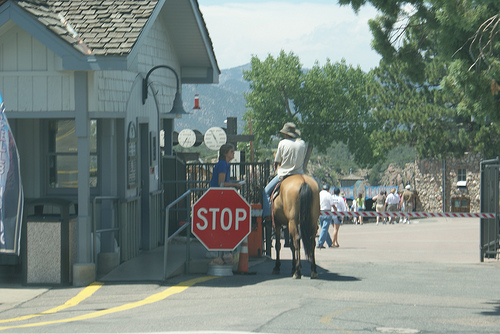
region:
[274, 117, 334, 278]
man riding a horse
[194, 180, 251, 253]
stop sign at the gate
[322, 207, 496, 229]
post is red and white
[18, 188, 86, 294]
trash can next to a building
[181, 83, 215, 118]
bird feeder hanging from roof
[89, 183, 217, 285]
railing to walk up to building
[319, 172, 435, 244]
people walking behind gate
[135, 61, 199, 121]
light hanging from the building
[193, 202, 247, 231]
stop is written in white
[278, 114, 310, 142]
man is wearing a hat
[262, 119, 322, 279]
a person on horseback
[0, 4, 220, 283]
part of a grey structure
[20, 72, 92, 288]
large stationary trash receptacle beside a pillar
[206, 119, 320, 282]
woman looking towards person mounted on horse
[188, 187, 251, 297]
a large stop sign close to the ground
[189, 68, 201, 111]
a hanging bird feeder with red liquid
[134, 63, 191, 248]
light on curved pole above entrance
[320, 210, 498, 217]
red and white striped barrier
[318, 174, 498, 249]
people walking around beyond barrier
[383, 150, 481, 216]
a structure with a stone wall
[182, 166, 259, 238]
red and white sign on pole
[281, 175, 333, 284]
horse with long tail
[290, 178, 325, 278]
horses tail is black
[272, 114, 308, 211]
man sitting on horse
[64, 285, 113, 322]
yellow lines on street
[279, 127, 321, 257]
man wearing blue jeans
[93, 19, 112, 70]
gray shingles on roof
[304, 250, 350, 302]
shadow under brown horse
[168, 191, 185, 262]
gray hand railing by sign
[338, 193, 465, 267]
red and white pole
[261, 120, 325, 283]
man riding on a horse.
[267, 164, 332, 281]
Brown horse on the street.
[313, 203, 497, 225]
Red and white crossbar.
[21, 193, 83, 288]
Trash can beside the building.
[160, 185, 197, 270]
Gray hand railing.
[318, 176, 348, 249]
People walking on the road.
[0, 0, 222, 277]
building in the background.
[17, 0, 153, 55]
Gray shingles on the roof.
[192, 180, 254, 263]
Stop sign in front of the woman.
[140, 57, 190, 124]
Light above the door.